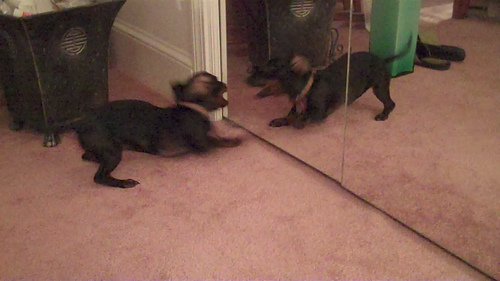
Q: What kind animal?
A: Dog.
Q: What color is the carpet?
A: Pink.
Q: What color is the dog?
A: Black.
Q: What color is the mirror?
A: Silver.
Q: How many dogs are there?
A: One.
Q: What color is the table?
A: Brown.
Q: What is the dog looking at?
A: Reflection.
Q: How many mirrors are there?
A: Two.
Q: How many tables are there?
A: One.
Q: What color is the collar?
A: White.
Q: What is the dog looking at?
A: Reflection.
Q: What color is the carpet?
A: Bright pink.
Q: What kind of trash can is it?
A: Metal.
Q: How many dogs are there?
A: One.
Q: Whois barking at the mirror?
A: A dog.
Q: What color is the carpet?
A: Pink.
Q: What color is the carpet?
A: Rose.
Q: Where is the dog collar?
A: Around its neck.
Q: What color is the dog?
A: Brown.